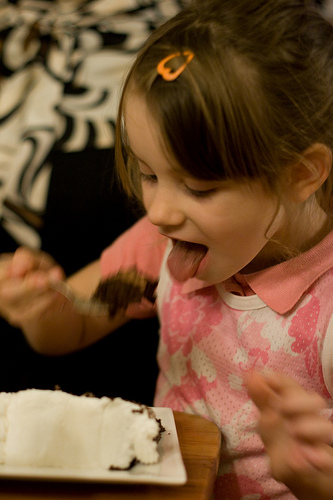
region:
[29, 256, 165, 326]
A piece of cake on a fork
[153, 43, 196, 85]
A barrett is orange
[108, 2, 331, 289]
A girl has brown hair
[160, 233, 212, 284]
A tongue of a girl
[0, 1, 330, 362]
A girl is eating chocolate cake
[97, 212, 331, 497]
A pink and white outfit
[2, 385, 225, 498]
A plate on the table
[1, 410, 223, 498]
A brown and wooden table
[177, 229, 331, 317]
A pink collar of a shirt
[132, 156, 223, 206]
A pair of eyes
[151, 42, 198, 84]
orange heart shaped barrette in hair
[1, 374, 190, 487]
slice of cake on plate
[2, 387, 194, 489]
square shaped plate on table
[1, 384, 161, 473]
white icing on top of cake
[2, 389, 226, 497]
wooden table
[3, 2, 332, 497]
little girl eating a piece of cake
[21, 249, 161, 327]
eating utensil with piece of cake on it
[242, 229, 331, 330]
peach lapel on shirt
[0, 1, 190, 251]
black and white blurred design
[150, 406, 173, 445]
piece of chocolate cake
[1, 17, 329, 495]
Little girl enjoying cake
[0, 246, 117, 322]
Blurry hand holding fork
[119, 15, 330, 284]
Blonde haired little girl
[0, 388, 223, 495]
White plate sitting on wood table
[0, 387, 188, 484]
Dessert sitting on white plate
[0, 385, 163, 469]
Chocolate cake covered by white frosting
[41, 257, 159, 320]
Blurry photo of fork holding cake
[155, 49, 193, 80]
Orange barrette in blonde hair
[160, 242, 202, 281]
Tongue sticking out of mouth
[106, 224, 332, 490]
Pink and white pullover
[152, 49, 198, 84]
orange metal hair beret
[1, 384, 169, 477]
chocolate cake with white frosting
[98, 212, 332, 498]
pink and white floral printed shirt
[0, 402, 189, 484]
white rectangular cake plate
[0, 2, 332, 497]
little girl eating cake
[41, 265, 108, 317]
stainless steel fork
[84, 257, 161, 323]
piece of chocolate cake going in the girls mouth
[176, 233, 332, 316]
pink collar of a polo shirt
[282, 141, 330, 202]
little girl's left ear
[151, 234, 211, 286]
little girls pink tongue